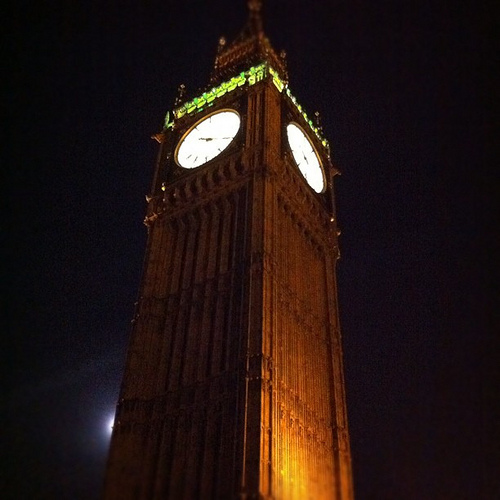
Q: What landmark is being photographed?
A: Big Ben.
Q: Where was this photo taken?
A: London.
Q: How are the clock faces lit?
A: With lights from inside them.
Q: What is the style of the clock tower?
A: Gothic revival.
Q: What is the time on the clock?
A: 10:20.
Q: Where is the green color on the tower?
A: Above the clock faces.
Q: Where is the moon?
A: Behind the tower.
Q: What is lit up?
A: Clock.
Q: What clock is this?
A: Big Ben.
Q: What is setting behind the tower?
A: Moon.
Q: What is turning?
A: The clock.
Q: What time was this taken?
A: 10:20.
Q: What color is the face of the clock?
A: White.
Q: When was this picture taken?
A: At night.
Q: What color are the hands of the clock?
A: Black.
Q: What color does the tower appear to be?
A: Gold.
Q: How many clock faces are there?
A: Two.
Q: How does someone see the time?
A: By looking up.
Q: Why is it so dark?
A: It's night time.